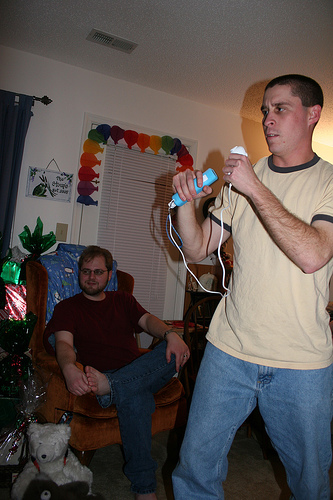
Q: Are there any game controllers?
A: Yes, there is a game controller.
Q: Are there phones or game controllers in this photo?
A: Yes, there is a game controller.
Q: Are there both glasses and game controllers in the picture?
A: Yes, there are both a game controller and glasses.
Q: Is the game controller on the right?
A: Yes, the game controller is on the right of the image.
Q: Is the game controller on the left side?
A: No, the game controller is on the right of the image.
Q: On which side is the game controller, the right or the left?
A: The game controller is on the right of the image.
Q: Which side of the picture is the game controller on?
A: The game controller is on the right of the image.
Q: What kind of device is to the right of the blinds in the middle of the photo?
A: The device is a game controller.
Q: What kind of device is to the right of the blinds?
A: The device is a game controller.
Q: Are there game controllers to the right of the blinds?
A: Yes, there is a game controller to the right of the blinds.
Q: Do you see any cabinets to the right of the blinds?
A: No, there is a game controller to the right of the blinds.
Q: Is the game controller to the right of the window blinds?
A: Yes, the game controller is to the right of the blinds.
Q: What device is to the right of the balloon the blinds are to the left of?
A: The device is a game controller.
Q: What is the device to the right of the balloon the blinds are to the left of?
A: The device is a game controller.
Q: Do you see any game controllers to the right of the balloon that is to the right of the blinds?
A: Yes, there is a game controller to the right of the balloon.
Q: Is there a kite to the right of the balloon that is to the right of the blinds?
A: No, there is a game controller to the right of the balloon.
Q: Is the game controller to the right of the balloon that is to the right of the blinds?
A: Yes, the game controller is to the right of the balloon.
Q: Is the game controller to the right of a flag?
A: No, the game controller is to the right of the balloon.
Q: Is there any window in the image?
A: Yes, there is a window.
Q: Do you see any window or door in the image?
A: Yes, there is a window.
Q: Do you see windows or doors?
A: Yes, there is a window.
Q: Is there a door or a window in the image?
A: Yes, there is a window.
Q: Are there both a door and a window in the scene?
A: No, there is a window but no doors.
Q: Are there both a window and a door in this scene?
A: No, there is a window but no doors.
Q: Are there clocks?
A: No, there are no clocks.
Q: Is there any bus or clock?
A: No, there are no clocks or buses.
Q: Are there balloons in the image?
A: Yes, there is a balloon.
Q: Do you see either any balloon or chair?
A: Yes, there is a balloon.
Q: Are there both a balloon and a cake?
A: No, there is a balloon but no cakes.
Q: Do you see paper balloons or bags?
A: Yes, there is a paper balloon.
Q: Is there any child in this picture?
A: No, there are no children.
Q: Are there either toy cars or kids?
A: No, there are no kids or toy cars.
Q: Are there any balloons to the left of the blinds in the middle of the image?
A: Yes, there is a balloon to the left of the blinds.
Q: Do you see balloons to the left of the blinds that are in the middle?
A: Yes, there is a balloon to the left of the blinds.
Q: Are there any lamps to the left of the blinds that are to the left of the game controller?
A: No, there is a balloon to the left of the blinds.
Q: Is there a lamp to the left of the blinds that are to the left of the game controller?
A: No, there is a balloon to the left of the blinds.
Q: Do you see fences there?
A: No, there are no fences.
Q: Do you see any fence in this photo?
A: No, there are no fences.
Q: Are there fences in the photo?
A: No, there are no fences.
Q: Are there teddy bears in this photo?
A: Yes, there is a teddy bear.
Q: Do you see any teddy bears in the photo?
A: Yes, there is a teddy bear.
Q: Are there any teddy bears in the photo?
A: Yes, there is a teddy bear.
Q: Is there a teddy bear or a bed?
A: Yes, there is a teddy bear.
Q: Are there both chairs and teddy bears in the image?
A: Yes, there are both a teddy bear and a chair.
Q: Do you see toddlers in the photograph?
A: No, there are no toddlers.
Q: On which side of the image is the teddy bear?
A: The teddy bear is on the left of the image.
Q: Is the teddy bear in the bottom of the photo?
A: Yes, the teddy bear is in the bottom of the image.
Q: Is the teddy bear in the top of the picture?
A: No, the teddy bear is in the bottom of the image.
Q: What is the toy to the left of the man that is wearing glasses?
A: The toy is a teddy bear.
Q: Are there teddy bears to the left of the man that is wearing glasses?
A: Yes, there is a teddy bear to the left of the man.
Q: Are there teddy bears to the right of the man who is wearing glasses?
A: No, the teddy bear is to the left of the man.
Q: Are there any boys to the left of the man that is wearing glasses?
A: No, there is a teddy bear to the left of the man.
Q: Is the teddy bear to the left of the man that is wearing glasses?
A: Yes, the teddy bear is to the left of the man.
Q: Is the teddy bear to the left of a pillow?
A: No, the teddy bear is to the left of the man.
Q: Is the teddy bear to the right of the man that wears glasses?
A: No, the teddy bear is to the left of the man.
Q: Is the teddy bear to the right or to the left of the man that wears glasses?
A: The teddy bear is to the left of the man.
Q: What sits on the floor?
A: The teddy bear sits on the floor.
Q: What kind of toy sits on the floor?
A: The toy is a teddy bear.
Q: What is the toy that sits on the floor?
A: The toy is a teddy bear.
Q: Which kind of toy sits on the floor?
A: The toy is a teddy bear.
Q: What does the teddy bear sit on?
A: The teddy bear sits on the floor.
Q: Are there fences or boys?
A: No, there are no fences or boys.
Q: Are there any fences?
A: No, there are no fences.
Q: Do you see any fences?
A: No, there are no fences.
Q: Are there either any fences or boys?
A: No, there are no fences or boys.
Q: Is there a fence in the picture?
A: No, there are no fences.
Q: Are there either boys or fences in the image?
A: No, there are no fences or boys.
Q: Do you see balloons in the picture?
A: Yes, there is a balloon.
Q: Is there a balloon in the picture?
A: Yes, there is a balloon.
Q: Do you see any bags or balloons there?
A: Yes, there is a balloon.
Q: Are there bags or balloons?
A: Yes, there is a balloon.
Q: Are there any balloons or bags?
A: Yes, there is a balloon.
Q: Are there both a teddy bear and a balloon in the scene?
A: Yes, there are both a balloon and a teddy bear.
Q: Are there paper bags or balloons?
A: Yes, there is a paper balloon.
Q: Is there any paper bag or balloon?
A: Yes, there is a paper balloon.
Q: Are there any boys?
A: No, there are no boys.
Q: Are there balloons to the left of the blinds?
A: Yes, there is a balloon to the left of the blinds.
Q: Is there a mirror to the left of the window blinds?
A: No, there is a balloon to the left of the blinds.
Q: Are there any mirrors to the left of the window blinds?
A: No, there is a balloon to the left of the blinds.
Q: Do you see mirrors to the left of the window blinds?
A: No, there is a balloon to the left of the blinds.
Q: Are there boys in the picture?
A: No, there are no boys.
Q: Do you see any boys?
A: No, there are no boys.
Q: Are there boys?
A: No, there are no boys.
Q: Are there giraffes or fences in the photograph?
A: No, there are no fences or giraffes.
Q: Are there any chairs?
A: Yes, there is a chair.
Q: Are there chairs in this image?
A: Yes, there is a chair.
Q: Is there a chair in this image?
A: Yes, there is a chair.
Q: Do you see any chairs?
A: Yes, there is a chair.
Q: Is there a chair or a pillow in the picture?
A: Yes, there is a chair.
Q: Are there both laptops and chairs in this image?
A: No, there is a chair but no laptops.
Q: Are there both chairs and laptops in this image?
A: No, there is a chair but no laptops.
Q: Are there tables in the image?
A: No, there are no tables.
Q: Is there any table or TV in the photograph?
A: No, there are no tables or televisions.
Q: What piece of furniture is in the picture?
A: The piece of furniture is a chair.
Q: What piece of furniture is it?
A: The piece of furniture is a chair.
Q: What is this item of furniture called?
A: This is a chair.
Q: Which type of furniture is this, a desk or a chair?
A: This is a chair.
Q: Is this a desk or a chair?
A: This is a chair.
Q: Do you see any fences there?
A: No, there are no fences.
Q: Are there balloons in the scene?
A: Yes, there is a balloon.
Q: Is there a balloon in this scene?
A: Yes, there is a balloon.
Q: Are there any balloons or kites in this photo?
A: Yes, there is a balloon.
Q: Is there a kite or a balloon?
A: Yes, there is a balloon.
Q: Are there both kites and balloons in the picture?
A: No, there is a balloon but no kites.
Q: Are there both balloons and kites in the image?
A: No, there is a balloon but no kites.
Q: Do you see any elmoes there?
A: No, there are no elmoes.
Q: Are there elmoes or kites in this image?
A: No, there are no elmoes or kites.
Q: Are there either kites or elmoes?
A: No, there are no elmoes or kites.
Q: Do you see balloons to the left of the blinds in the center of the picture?
A: Yes, there is a balloon to the left of the blinds.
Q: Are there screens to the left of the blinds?
A: No, there is a balloon to the left of the blinds.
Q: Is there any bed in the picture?
A: No, there are no beds.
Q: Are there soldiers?
A: No, there are no soldiers.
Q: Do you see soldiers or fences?
A: No, there are no soldiers or fences.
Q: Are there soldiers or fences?
A: No, there are no soldiers or fences.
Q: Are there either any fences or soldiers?
A: No, there are no soldiers or fences.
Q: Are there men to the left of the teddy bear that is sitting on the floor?
A: No, the man is to the right of the teddy bear.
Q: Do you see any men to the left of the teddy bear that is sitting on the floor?
A: No, the man is to the right of the teddy bear.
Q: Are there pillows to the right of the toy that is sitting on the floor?
A: No, there is a man to the right of the teddy bear.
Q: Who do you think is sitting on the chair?
A: The man is sitting on the chair.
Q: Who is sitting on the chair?
A: The man is sitting on the chair.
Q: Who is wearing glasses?
A: The man is wearing glasses.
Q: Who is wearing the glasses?
A: The man is wearing glasses.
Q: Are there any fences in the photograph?
A: No, there are no fences.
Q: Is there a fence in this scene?
A: No, there are no fences.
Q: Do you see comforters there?
A: No, there are no comforters.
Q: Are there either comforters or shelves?
A: No, there are no comforters or shelves.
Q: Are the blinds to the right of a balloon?
A: Yes, the blinds are to the right of a balloon.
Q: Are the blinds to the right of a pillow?
A: No, the blinds are to the right of a balloon.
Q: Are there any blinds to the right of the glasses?
A: Yes, there are blinds to the right of the glasses.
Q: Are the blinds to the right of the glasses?
A: Yes, the blinds are to the right of the glasses.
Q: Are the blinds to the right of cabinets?
A: No, the blinds are to the right of the glasses.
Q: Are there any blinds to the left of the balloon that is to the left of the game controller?
A: Yes, there are blinds to the left of the balloon.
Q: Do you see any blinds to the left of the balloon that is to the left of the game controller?
A: Yes, there are blinds to the left of the balloon.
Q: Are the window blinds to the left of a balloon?
A: Yes, the blinds are to the left of a balloon.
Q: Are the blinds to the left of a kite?
A: No, the blinds are to the left of a balloon.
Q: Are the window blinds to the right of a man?
A: No, the blinds are to the left of a man.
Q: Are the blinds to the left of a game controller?
A: Yes, the blinds are to the left of a game controller.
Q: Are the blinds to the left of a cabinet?
A: No, the blinds are to the left of a game controller.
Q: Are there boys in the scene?
A: No, there are no boys.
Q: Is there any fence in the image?
A: No, there are no fences.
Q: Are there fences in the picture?
A: No, there are no fences.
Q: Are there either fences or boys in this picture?
A: No, there are no fences or boys.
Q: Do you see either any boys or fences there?
A: No, there are no fences or boys.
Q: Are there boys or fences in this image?
A: No, there are no fences or boys.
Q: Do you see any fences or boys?
A: No, there are no fences or boys.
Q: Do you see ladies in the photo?
A: No, there are no ladies.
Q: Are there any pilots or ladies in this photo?
A: No, there are no ladies or pilots.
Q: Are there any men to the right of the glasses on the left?
A: Yes, there is a man to the right of the glasses.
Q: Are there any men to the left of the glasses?
A: No, the man is to the right of the glasses.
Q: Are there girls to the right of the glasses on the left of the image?
A: No, there is a man to the right of the glasses.